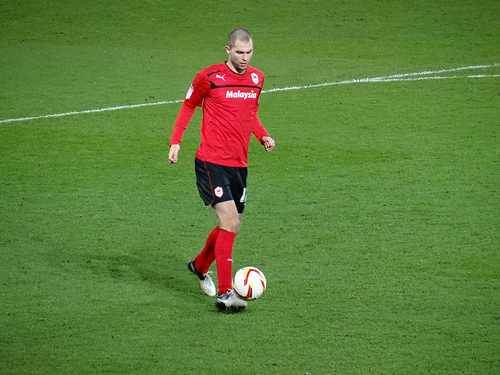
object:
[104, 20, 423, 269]
green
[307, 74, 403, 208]
field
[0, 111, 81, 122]
white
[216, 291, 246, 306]
gray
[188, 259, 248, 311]
black shoes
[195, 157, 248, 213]
black shorts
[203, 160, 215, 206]
pinstripe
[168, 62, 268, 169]
red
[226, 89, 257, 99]
name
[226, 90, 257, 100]
team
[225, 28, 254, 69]
head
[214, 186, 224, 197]
logo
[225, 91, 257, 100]
white puma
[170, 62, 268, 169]
jersey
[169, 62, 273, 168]
mean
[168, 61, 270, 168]
red shirt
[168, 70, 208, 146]
sleeves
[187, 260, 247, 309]
feet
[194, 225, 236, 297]
long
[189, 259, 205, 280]
black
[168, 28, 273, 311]
man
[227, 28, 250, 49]
hair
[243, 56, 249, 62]
nose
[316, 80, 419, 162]
section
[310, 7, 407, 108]
grass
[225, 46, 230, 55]
ear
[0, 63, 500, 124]
line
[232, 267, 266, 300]
ball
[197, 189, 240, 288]
legs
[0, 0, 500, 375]
play ground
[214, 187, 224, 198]
symbol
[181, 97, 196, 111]
elbow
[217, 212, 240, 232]
knee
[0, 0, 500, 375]
ground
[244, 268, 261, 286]
white,red,yellow